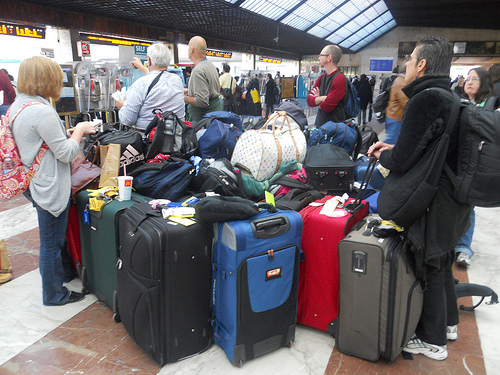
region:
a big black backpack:
[439, 102, 499, 204]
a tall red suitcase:
[292, 151, 379, 339]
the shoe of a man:
[403, 335, 449, 362]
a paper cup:
[119, 174, 133, 203]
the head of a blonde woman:
[15, 57, 64, 101]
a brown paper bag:
[94, 142, 121, 190]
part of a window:
[237, 0, 298, 17]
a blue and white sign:
[368, 57, 398, 74]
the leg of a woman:
[32, 204, 66, 303]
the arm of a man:
[320, 72, 348, 107]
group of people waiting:
[17, 10, 494, 360]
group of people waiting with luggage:
[28, 41, 486, 291]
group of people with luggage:
[38, 68, 473, 372]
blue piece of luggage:
[195, 207, 287, 374]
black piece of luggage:
[94, 188, 209, 373]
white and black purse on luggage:
[234, 85, 319, 190]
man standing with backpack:
[364, 27, 495, 332]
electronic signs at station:
[248, 5, 390, 62]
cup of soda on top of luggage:
[104, 162, 142, 207]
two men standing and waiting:
[115, 31, 233, 136]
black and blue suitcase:
[216, 203, 302, 364]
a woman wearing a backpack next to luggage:
[0, 57, 102, 306]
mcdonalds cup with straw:
[117, 160, 132, 198]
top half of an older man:
[185, 35, 222, 113]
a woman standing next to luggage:
[367, 35, 498, 372]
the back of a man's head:
[144, 44, 174, 71]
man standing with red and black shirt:
[308, 45, 359, 123]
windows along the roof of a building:
[218, 0, 395, 35]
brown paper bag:
[97, 142, 119, 190]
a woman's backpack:
[1, 105, 46, 197]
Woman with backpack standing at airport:
[0, 50, 110, 315]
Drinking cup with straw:
[108, 160, 139, 206]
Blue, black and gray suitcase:
[210, 203, 301, 369]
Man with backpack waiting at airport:
[362, 27, 497, 362]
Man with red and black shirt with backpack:
[301, 35, 367, 121]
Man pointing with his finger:
[105, 36, 186, 131]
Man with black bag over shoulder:
[360, 30, 460, 226]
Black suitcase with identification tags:
[108, 191, 209, 367]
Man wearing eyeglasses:
[311, 37, 346, 77]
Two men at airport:
[112, 28, 229, 121]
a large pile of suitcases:
[73, 99, 433, 359]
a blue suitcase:
[209, 201, 306, 369]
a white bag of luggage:
[228, 110, 323, 188]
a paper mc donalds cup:
[116, 167, 138, 200]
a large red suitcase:
[298, 194, 368, 346]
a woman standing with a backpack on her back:
[3, 57, 93, 312]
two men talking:
[114, 25, 256, 136]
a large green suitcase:
[77, 181, 157, 329]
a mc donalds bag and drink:
[88, 135, 134, 218]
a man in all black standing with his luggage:
[374, 33, 493, 373]